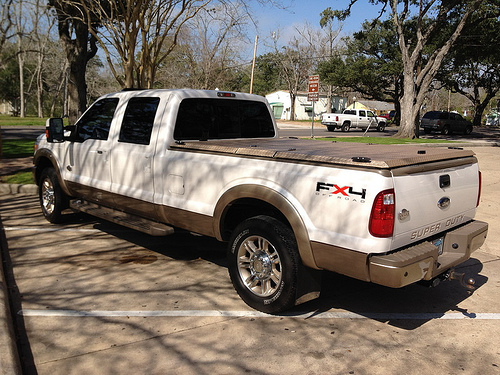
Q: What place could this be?
A: It is a parking lot.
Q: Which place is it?
A: It is a parking lot.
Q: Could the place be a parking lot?
A: Yes, it is a parking lot.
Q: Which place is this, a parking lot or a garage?
A: It is a parking lot.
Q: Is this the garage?
A: No, it is the parking lot.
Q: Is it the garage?
A: No, it is the parking lot.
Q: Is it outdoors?
A: Yes, it is outdoors.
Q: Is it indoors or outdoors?
A: It is outdoors.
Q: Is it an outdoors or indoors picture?
A: It is outdoors.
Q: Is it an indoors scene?
A: No, it is outdoors.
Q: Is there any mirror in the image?
A: Yes, there is a mirror.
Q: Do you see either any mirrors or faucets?
A: Yes, there is a mirror.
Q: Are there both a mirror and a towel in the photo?
A: No, there is a mirror but no towels.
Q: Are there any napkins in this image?
A: No, there are no napkins.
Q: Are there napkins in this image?
A: No, there are no napkins.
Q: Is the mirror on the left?
A: Yes, the mirror is on the left of the image.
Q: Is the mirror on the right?
A: No, the mirror is on the left of the image.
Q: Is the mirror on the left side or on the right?
A: The mirror is on the left of the image.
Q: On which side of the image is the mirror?
A: The mirror is on the left of the image.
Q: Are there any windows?
A: Yes, there is a window.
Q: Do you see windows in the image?
A: Yes, there is a window.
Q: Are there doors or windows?
A: Yes, there is a window.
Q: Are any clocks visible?
A: No, there are no clocks.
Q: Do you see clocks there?
A: No, there are no clocks.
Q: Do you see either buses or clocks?
A: No, there are no clocks or buses.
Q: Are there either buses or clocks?
A: No, there are no clocks or buses.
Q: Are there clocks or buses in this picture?
A: No, there are no clocks or buses.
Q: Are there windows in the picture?
A: Yes, there is a window.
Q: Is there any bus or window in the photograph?
A: Yes, there is a window.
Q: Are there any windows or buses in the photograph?
A: Yes, there is a window.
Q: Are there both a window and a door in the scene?
A: Yes, there are both a window and a door.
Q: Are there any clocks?
A: No, there are no clocks.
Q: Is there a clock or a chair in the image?
A: No, there are no clocks or chairs.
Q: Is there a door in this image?
A: Yes, there is a door.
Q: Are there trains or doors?
A: Yes, there is a door.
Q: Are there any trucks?
A: Yes, there is a truck.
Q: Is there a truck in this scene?
A: Yes, there is a truck.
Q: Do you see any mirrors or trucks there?
A: Yes, there is a truck.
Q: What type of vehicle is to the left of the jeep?
A: The vehicle is a truck.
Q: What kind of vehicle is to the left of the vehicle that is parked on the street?
A: The vehicle is a truck.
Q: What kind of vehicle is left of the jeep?
A: The vehicle is a truck.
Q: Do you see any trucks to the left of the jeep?
A: Yes, there is a truck to the left of the jeep.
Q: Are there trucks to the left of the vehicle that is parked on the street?
A: Yes, there is a truck to the left of the jeep.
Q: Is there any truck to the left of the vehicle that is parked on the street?
A: Yes, there is a truck to the left of the jeep.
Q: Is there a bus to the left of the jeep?
A: No, there is a truck to the left of the jeep.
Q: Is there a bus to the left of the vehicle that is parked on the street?
A: No, there is a truck to the left of the jeep.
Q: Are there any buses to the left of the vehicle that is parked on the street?
A: No, there is a truck to the left of the jeep.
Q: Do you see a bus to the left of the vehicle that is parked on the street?
A: No, there is a truck to the left of the jeep.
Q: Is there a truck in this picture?
A: Yes, there is a truck.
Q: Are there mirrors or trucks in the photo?
A: Yes, there is a truck.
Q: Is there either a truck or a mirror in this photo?
A: Yes, there is a truck.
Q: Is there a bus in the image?
A: No, there are no buses.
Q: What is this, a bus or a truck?
A: This is a truck.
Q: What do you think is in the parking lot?
A: The truck is in the parking lot.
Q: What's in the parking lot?
A: The truck is in the parking lot.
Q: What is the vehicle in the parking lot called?
A: The vehicle is a truck.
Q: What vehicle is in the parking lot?
A: The vehicle is a truck.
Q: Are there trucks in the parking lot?
A: Yes, there is a truck in the parking lot.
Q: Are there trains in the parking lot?
A: No, there is a truck in the parking lot.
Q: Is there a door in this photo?
A: Yes, there is a door.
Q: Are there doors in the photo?
A: Yes, there is a door.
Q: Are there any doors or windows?
A: Yes, there is a door.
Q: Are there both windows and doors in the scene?
A: Yes, there are both a door and a window.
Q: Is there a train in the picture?
A: No, there are no trains.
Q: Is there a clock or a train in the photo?
A: No, there are no trains or clocks.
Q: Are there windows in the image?
A: Yes, there is a window.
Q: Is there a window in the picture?
A: Yes, there is a window.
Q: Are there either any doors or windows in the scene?
A: Yes, there is a window.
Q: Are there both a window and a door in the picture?
A: Yes, there are both a window and a door.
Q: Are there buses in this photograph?
A: No, there are no buses.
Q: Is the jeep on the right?
A: Yes, the jeep is on the right of the image.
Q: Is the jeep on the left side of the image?
A: No, the jeep is on the right of the image.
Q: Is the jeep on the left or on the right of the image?
A: The jeep is on the right of the image.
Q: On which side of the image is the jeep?
A: The jeep is on the right of the image.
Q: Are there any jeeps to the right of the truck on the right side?
A: Yes, there is a jeep to the right of the truck.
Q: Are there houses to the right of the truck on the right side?
A: No, there is a jeep to the right of the truck.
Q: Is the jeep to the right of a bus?
A: No, the jeep is to the right of the truck.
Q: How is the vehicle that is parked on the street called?
A: The vehicle is a jeep.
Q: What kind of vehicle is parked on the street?
A: The vehicle is a jeep.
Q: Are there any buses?
A: No, there are no buses.